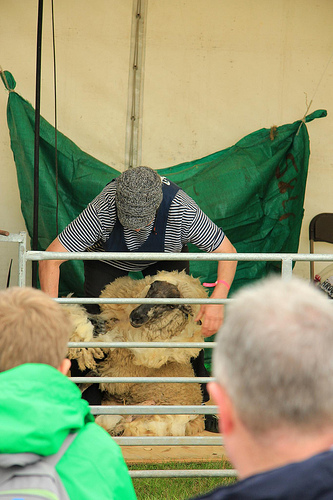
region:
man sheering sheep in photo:
[35, 156, 267, 448]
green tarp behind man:
[2, 65, 300, 298]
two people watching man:
[8, 255, 331, 487]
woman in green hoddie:
[0, 274, 117, 497]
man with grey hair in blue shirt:
[193, 239, 331, 497]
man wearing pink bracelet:
[197, 255, 253, 358]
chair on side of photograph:
[263, 179, 331, 279]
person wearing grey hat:
[69, 154, 205, 259]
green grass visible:
[113, 430, 213, 499]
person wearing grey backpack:
[3, 342, 123, 490]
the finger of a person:
[194, 303, 201, 320]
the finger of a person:
[197, 315, 203, 329]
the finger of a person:
[202, 319, 209, 336]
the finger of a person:
[202, 317, 215, 344]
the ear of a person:
[215, 313, 222, 330]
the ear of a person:
[202, 374, 229, 434]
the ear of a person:
[59, 351, 67, 380]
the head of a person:
[202, 267, 330, 474]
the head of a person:
[0, 279, 83, 372]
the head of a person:
[118, 164, 164, 229]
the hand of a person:
[192, 294, 226, 339]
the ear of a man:
[202, 373, 240, 435]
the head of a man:
[207, 268, 331, 479]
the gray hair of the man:
[208, 269, 331, 442]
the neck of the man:
[235, 427, 331, 480]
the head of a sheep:
[123, 273, 205, 331]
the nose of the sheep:
[124, 310, 146, 325]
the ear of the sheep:
[179, 300, 206, 327]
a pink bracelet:
[198, 273, 237, 293]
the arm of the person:
[182, 197, 242, 307]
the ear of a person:
[57, 357, 74, 380]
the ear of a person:
[191, 306, 205, 321]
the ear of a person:
[199, 313, 208, 339]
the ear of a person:
[207, 318, 215, 344]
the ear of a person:
[209, 319, 220, 339]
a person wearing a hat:
[34, 150, 227, 299]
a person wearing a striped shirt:
[36, 141, 241, 297]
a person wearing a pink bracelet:
[90, 156, 249, 298]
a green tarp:
[1, 61, 331, 293]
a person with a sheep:
[40, 162, 251, 430]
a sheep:
[34, 257, 252, 447]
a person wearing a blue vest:
[58, 143, 266, 350]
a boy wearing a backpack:
[3, 281, 161, 495]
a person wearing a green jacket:
[0, 267, 159, 496]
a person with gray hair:
[196, 264, 332, 479]